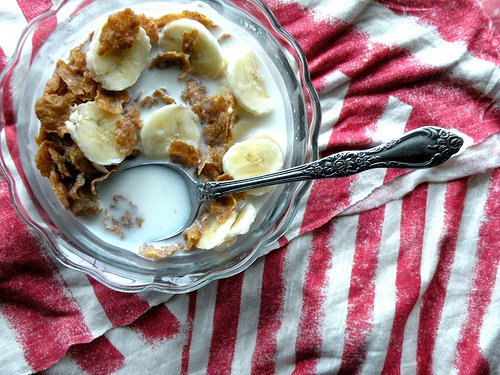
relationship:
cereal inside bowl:
[86, 23, 276, 240] [18, 23, 332, 291]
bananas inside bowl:
[42, 39, 301, 199] [18, 23, 332, 291]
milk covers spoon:
[134, 94, 194, 253] [117, 116, 455, 232]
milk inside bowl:
[134, 94, 194, 253] [18, 23, 332, 291]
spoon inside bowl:
[117, 116, 455, 232] [18, 23, 332, 291]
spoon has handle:
[117, 116, 455, 232] [311, 123, 465, 181]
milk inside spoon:
[134, 94, 194, 253] [117, 116, 455, 232]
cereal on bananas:
[86, 23, 276, 240] [42, 39, 301, 199]